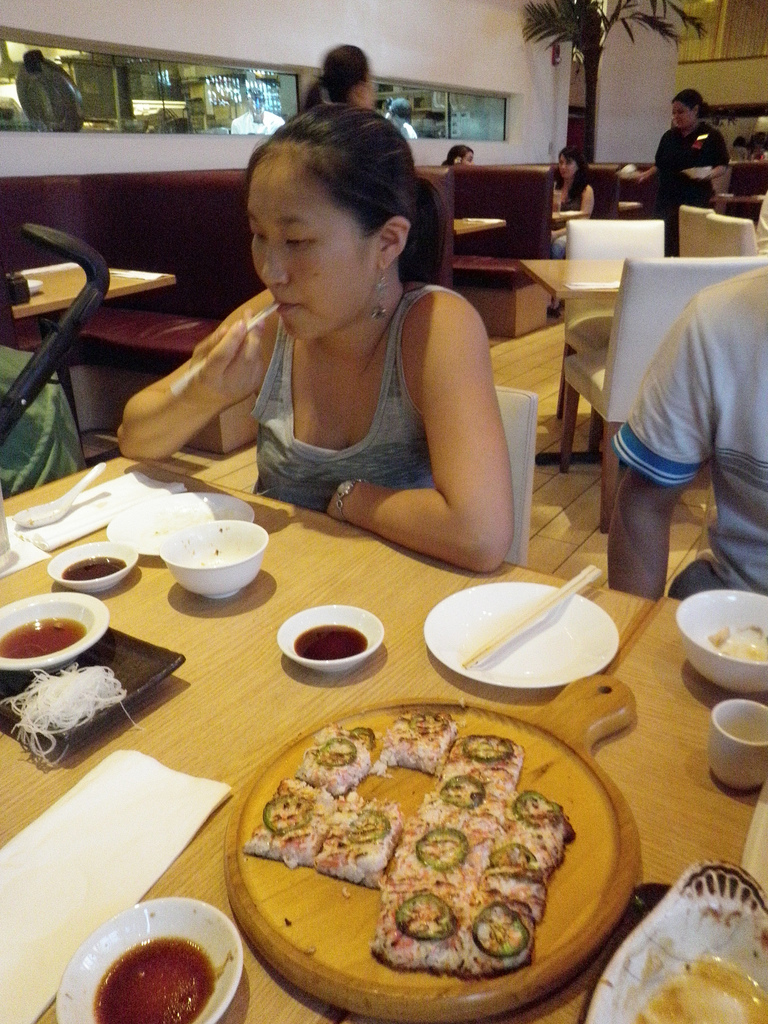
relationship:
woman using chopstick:
[104, 91, 518, 582] [460, 556, 595, 660]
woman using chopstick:
[104, 91, 518, 582] [460, 556, 609, 673]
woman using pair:
[104, 91, 518, 582] [168, 301, 276, 395]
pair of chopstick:
[168, 301, 276, 395] [460, 556, 595, 660]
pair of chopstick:
[168, 301, 276, 395] [460, 556, 609, 673]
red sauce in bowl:
[97, 934, 218, 1021] [54, 880, 220, 1005]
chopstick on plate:
[460, 556, 595, 660] [420, 580, 619, 688]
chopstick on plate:
[460, 556, 609, 673] [420, 580, 619, 688]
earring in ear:
[355, 265, 417, 330] [347, 203, 432, 288]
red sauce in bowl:
[97, 934, 217, 1020] [52, 899, 248, 1021]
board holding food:
[226, 674, 647, 1016] [262, 675, 626, 1009]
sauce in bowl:
[298, 625, 366, 655] [275, 601, 385, 674]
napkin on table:
[3, 746, 234, 1022] [2, 453, 763, 1022]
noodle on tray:
[3, 666, 137, 769] [0, 622, 190, 751]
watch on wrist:
[334, 475, 364, 523] [330, 479, 362, 520]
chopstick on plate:
[460, 556, 595, 660] [422, 572, 626, 697]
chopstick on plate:
[460, 556, 609, 673] [422, 572, 626, 697]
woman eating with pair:
[104, 91, 518, 582] [168, 301, 276, 396]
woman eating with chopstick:
[104, 91, 518, 582] [460, 556, 595, 660]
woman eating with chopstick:
[104, 91, 518, 582] [460, 556, 609, 673]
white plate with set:
[424, 589, 489, 638] [455, 566, 601, 674]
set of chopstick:
[455, 566, 601, 674] [460, 556, 595, 660]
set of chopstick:
[455, 566, 601, 674] [460, 556, 609, 673]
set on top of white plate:
[455, 566, 601, 674] [424, 589, 489, 638]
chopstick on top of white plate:
[460, 556, 595, 660] [424, 589, 489, 638]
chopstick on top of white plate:
[460, 556, 609, 673] [424, 589, 489, 638]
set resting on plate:
[455, 566, 602, 675] [420, 580, 619, 688]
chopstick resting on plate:
[460, 556, 609, 673] [420, 580, 619, 688]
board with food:
[226, 674, 647, 1016] [248, 705, 580, 969]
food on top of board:
[248, 705, 580, 969] [226, 674, 647, 1016]